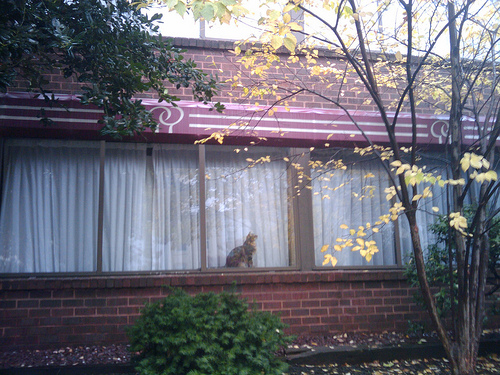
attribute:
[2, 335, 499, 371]
leaves — dry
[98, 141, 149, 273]
curtain — white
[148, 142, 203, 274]
curtain — white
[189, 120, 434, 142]
line — white, long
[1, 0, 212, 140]
leaves — green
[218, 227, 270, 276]
cat — sitting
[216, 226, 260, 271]
cat — inside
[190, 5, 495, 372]
tree — bare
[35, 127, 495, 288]
windows — glass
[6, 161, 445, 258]
curtains — white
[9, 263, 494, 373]
wall — lower